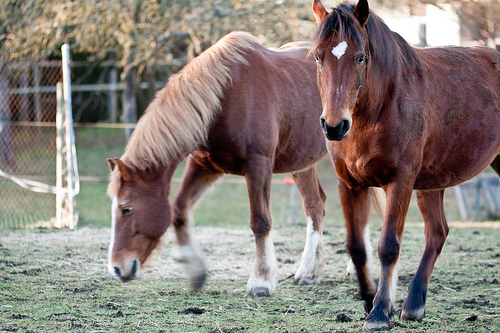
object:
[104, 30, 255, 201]
mane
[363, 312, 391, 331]
hoof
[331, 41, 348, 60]
spot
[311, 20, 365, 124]
face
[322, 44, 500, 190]
fur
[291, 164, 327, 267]
leg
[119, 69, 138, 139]
trunk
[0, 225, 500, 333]
grass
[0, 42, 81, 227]
fence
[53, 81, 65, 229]
pole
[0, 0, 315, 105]
branches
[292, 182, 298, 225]
pole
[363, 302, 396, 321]
hoof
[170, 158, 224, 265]
leg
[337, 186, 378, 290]
leg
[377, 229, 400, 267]
patches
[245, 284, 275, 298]
feet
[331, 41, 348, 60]
patch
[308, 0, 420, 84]
nose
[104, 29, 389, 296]
horse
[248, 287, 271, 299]
hooves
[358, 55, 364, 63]
eyes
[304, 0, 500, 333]
horse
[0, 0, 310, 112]
trees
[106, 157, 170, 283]
head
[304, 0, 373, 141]
head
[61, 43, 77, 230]
post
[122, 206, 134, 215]
eye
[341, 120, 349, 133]
nostrils